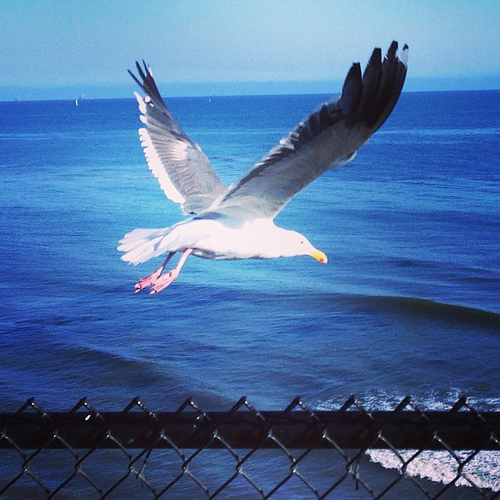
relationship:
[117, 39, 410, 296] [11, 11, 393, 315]
bird in sky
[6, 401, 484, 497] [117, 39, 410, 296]
fence next to bird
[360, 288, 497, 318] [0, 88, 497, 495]
wave in water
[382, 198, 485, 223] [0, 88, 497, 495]
wave in water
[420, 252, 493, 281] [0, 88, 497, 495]
wave in water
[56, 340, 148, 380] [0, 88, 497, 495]
wave in water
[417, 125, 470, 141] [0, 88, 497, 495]
wave in water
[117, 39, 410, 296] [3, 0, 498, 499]
bird above water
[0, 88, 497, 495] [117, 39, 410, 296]
water below bird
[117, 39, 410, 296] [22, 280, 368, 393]
bird above water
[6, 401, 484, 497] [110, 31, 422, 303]
fence behind bird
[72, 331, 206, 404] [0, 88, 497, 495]
wave on water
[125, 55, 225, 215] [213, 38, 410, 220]
wing of feathers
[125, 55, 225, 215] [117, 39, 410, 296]
wing of bird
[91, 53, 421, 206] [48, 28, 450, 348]
feathers on bird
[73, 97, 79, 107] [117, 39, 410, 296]
boat far from bird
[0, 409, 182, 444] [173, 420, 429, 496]
rod with fencing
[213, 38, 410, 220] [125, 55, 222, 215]
feathers of wing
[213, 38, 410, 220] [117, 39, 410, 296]
feathers of bird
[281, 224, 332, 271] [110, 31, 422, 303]
head of bird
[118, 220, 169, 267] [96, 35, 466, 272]
tail of bird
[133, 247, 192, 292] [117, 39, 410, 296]
legs of bird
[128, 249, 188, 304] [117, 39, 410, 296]
feet of bird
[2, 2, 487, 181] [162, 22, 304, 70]
sky has some clouds